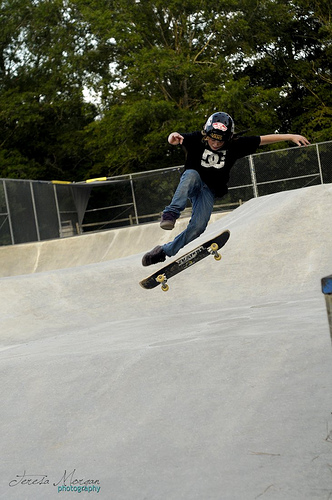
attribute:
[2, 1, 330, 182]
trees — green, tall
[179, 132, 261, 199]
t-shirt — black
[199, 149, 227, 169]
design — white 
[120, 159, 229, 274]
pants — blue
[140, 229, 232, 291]
skateboard — black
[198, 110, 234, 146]
helmet — black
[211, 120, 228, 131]
sticker — white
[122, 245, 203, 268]
shoes — Black   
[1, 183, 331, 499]
boarding area — Grey , concrete  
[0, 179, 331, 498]
ground — white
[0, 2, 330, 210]
trees — Green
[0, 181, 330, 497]
skateboard park — grey, concrete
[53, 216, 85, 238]
trash can — Grey 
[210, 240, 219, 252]
wheel — yellow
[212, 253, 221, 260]
wheel — yellow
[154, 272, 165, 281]
wheel — yellow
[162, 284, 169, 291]
wheel — yellow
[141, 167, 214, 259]
jeans — blue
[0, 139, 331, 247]
fence — silver, chain link 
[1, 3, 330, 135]
sky — clear, white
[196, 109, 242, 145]
helmet — black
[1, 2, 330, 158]
trees — large, leafy